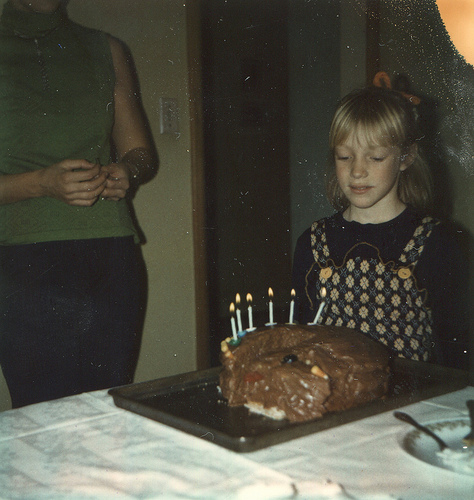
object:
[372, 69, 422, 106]
ribbon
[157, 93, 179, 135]
light switch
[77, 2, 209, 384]
wall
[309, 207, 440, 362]
dress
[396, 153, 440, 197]
ground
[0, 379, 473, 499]
tablecloth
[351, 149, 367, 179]
nose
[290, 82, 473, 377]
girl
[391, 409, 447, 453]
fork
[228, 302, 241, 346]
candle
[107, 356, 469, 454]
pan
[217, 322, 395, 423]
cake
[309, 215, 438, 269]
suspenders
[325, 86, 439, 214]
blonde hair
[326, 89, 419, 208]
girl's head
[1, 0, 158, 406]
woman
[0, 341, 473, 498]
table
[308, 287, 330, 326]
candle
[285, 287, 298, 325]
candle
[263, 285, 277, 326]
candle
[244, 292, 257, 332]
candle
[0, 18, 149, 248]
shirt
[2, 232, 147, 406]
jeans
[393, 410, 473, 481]
dish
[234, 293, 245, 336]
candle